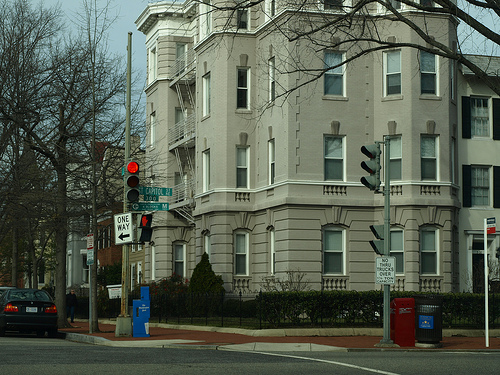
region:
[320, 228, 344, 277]
the rectangle window of the building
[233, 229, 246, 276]
the rectangle window of the building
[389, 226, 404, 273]
the rectangle window of the building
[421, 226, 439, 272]
the rectangle window of the building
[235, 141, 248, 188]
the rectangle window of the building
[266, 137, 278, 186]
the rectangle window of the building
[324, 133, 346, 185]
the rectangle window of the building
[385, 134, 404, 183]
the rectangle window of the building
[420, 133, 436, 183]
the rectangle window of the building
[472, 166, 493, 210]
the rectangle window of the building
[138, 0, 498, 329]
Large building on the corner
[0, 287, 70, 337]
Car parked at the curb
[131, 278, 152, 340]
Newspaper box on the curb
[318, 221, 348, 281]
Window on the building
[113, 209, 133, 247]
One Way sign on post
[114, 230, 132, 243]
Arrow pointing left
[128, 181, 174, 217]
Street signs on the post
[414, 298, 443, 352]
Garbage bin on the sidewalk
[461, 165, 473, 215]
Black shutter on the window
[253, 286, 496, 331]
Hedges in front of building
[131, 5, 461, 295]
gray building with white windows and trim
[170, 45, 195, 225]
outdoor metal staircases on side of wall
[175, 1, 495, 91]
tree branches curving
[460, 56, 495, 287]
tan building with black shutters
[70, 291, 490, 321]
hedges and railing around buildings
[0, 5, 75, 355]
dark car parked under tree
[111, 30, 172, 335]
pole supporting traffic signal and signs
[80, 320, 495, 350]
brick sidewalk within gray curb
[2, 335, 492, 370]
dark gray street with white line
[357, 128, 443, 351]
traffic signals on pole next to containers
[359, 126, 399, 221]
Street lights on a pole.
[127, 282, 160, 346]
A blue newspaper box.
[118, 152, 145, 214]
A traffic light indicating stop.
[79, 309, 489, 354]
A red sidewalk.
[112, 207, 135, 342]
A crooked one way sign on a post.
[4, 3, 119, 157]
A blue sky behind bare branches.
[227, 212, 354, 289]
Three arched windows.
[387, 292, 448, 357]
Newspapers for sale beside a trash can.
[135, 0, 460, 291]
A beautiful building with unusual architecture.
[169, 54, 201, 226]
Balconies with fire escapes.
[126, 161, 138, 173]
red light signal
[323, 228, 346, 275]
tall window of building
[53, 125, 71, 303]
tall trunk of tree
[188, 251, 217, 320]
green tree in front of building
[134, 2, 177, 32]
white design made on building wall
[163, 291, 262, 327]
fence of building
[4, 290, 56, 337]
car parked near tree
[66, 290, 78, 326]
man walking on pedestrian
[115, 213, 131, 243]
ONE WAY mentioned on sign board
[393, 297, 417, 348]
red color bin kept near signal pole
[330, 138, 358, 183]
a window on the building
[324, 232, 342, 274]
a window on the building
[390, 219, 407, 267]
a window on the building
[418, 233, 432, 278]
a window on the building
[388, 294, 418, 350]
a red newspaper box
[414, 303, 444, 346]
a black newspaper stand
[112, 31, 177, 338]
a pole with signs and a light on it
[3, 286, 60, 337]
the back of a blue car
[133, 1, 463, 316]
a gray house with many windows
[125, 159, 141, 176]
a red traffic light